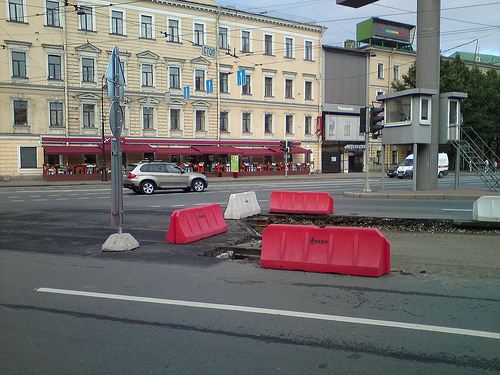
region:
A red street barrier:
[171, 201, 266, 248]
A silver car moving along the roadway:
[131, 154, 223, 201]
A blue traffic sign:
[197, 77, 233, 107]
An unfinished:
[267, 193, 457, 263]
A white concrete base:
[92, 225, 159, 266]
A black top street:
[28, 253, 245, 340]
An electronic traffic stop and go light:
[336, 77, 396, 162]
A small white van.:
[401, 162, 413, 180]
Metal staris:
[462, 141, 485, 166]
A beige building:
[166, 17, 286, 89]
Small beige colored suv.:
[121, 158, 210, 195]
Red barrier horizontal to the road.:
[256, 219, 392, 277]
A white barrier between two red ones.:
[222, 188, 264, 220]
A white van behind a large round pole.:
[391, 147, 451, 177]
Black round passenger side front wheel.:
[188, 177, 205, 192]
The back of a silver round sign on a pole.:
[105, 101, 125, 140]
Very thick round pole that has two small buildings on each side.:
[412, 0, 440, 190]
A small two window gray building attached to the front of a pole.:
[375, 86, 439, 149]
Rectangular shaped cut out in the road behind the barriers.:
[205, 217, 499, 283]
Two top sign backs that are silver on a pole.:
[102, 45, 129, 136]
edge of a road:
[394, 260, 424, 285]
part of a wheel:
[181, 160, 209, 197]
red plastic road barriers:
[140, 161, 414, 290]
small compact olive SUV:
[108, 144, 228, 220]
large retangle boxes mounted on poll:
[369, 81, 486, 144]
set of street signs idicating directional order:
[92, 51, 140, 259]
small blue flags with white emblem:
[154, 71, 275, 104]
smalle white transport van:
[385, 147, 454, 183]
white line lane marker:
[17, 247, 476, 359]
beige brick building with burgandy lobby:
[22, 54, 332, 180]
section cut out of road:
[208, 190, 493, 301]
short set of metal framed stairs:
[429, 118, 499, 195]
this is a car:
[126, 155, 209, 193]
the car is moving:
[127, 155, 209, 195]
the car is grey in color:
[161, 174, 180, 186]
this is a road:
[208, 293, 353, 370]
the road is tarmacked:
[241, 321, 368, 373]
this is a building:
[185, 23, 304, 117]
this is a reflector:
[259, 222, 394, 278]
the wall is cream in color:
[295, 61, 316, 76]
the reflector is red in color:
[323, 234, 373, 266]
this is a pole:
[90, 112, 142, 247]